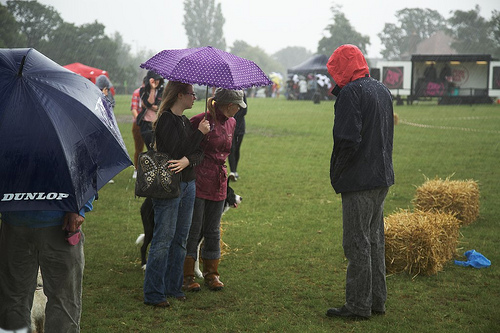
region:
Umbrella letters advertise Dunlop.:
[3, 42, 131, 267]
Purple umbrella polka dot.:
[133, 44, 286, 108]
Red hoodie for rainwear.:
[312, 40, 399, 181]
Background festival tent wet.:
[280, 47, 358, 116]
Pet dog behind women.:
[139, 180, 247, 270]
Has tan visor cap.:
[198, 85, 255, 157]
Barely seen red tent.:
[57, 56, 128, 106]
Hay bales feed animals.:
[380, 169, 488, 277]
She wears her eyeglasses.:
[157, 75, 200, 128]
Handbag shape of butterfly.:
[129, 114, 189, 209]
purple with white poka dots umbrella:
[140, 45, 272, 90]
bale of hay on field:
[376, 205, 461, 270]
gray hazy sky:
[5, 0, 497, 55]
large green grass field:
[72, 90, 492, 326]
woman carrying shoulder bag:
[145, 80, 206, 315]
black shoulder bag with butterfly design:
[131, 111, 181, 196]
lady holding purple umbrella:
[187, 90, 242, 290]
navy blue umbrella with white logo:
[0, 45, 130, 230]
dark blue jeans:
[142, 177, 192, 298]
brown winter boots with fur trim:
[182, 245, 224, 291]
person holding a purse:
[130, 77, 205, 309]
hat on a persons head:
[211, 82, 251, 121]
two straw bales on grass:
[378, 172, 495, 294]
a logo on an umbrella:
[0, 180, 82, 218]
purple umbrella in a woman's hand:
[138, 39, 275, 136]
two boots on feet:
[179, 248, 227, 296]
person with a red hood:
[316, 36, 400, 136]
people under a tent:
[280, 45, 338, 105]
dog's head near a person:
[211, 163, 249, 223]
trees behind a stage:
[378, 4, 499, 79]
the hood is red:
[309, 35, 376, 81]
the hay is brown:
[390, 211, 455, 256]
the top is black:
[337, 98, 395, 175]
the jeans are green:
[137, 207, 197, 282]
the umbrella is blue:
[16, 103, 126, 183]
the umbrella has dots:
[165, 50, 278, 78]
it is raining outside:
[40, 13, 495, 308]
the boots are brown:
[195, 265, 225, 292]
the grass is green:
[441, 130, 461, 183]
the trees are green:
[53, 25, 117, 50]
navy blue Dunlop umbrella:
[5, 68, 112, 223]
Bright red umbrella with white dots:
[59, 63, 109, 94]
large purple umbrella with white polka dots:
[137, 39, 284, 89]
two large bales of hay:
[381, 173, 478, 298]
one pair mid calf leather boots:
[176, 248, 248, 307]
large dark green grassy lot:
[238, 111, 321, 311]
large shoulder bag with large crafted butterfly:
[121, 123, 191, 205]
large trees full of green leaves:
[5, 6, 492, 47]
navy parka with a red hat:
[301, 45, 417, 198]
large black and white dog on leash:
[116, 186, 267, 269]